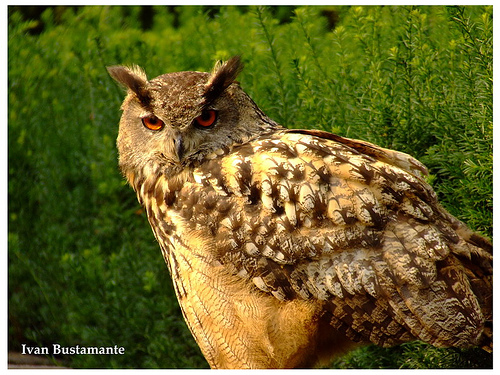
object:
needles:
[249, 3, 292, 117]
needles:
[292, 6, 348, 130]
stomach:
[170, 232, 301, 375]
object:
[267, 18, 474, 136]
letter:
[20, 343, 27, 353]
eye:
[140, 113, 165, 131]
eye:
[191, 105, 219, 129]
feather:
[365, 222, 442, 290]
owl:
[104, 51, 494, 371]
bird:
[103, 56, 495, 369]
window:
[102, 53, 499, 366]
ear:
[203, 51, 252, 103]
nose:
[173, 138, 184, 146]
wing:
[210, 134, 391, 228]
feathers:
[168, 118, 494, 356]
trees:
[293, 19, 498, 139]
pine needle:
[385, 45, 400, 68]